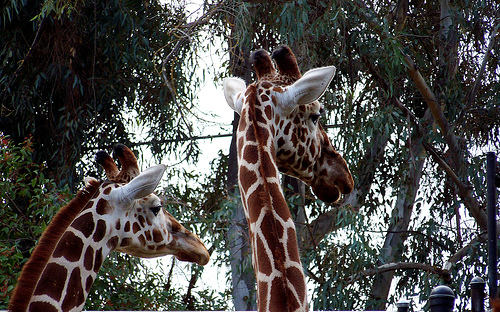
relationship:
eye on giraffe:
[309, 111, 319, 122] [221, 44, 355, 312]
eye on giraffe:
[149, 205, 160, 215] [8, 142, 209, 309]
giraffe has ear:
[221, 44, 355, 312] [284, 64, 335, 106]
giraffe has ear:
[221, 44, 355, 312] [223, 80, 245, 114]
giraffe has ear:
[8, 142, 209, 309] [112, 162, 166, 209]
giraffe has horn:
[226, 49, 351, 306] [271, 43, 301, 80]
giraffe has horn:
[226, 49, 351, 306] [248, 49, 277, 80]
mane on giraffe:
[5, 176, 97, 310] [8, 142, 209, 309]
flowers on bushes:
[4, 131, 179, 310] [7, 102, 72, 251]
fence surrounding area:
[316, 150, 453, 304] [4, 2, 499, 310]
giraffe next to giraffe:
[221, 44, 355, 312] [8, 142, 209, 309]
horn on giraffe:
[268, 44, 302, 78] [187, 37, 328, 302]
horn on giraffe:
[249, 49, 279, 83] [187, 37, 328, 302]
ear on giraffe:
[287, 63, 337, 110] [197, 33, 397, 307]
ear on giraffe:
[222, 85, 248, 115] [197, 33, 397, 307]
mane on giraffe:
[246, 84, 290, 308] [221, 44, 355, 312]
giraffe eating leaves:
[221, 44, 355, 312] [0, 0, 498, 310]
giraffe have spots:
[221, 44, 355, 312] [48, 230, 86, 302]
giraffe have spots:
[8, 142, 209, 309] [244, 166, 299, 288]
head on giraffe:
[208, 38, 363, 215] [214, 28, 344, 227]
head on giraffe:
[100, 168, 199, 276] [41, 202, 106, 294]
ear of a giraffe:
[117, 159, 177, 206] [30, 87, 227, 300]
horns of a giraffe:
[94, 142, 139, 178] [8, 142, 209, 309]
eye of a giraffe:
[149, 205, 164, 217] [8, 142, 209, 309]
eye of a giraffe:
[309, 112, 321, 126] [221, 44, 355, 312]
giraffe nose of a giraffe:
[192, 238, 210, 266] [55, 138, 170, 310]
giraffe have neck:
[221, 44, 355, 312] [236, 142, 306, 309]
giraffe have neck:
[8, 142, 209, 309] [11, 201, 107, 308]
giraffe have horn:
[221, 44, 355, 312] [251, 44, 302, 79]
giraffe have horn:
[8, 142, 209, 309] [93, 140, 140, 179]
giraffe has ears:
[221, 44, 355, 312] [218, 62, 339, 116]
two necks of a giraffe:
[338, 15, 420, 76] [221, 44, 355, 312]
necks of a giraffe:
[5, 188, 108, 309] [8, 142, 209, 309]